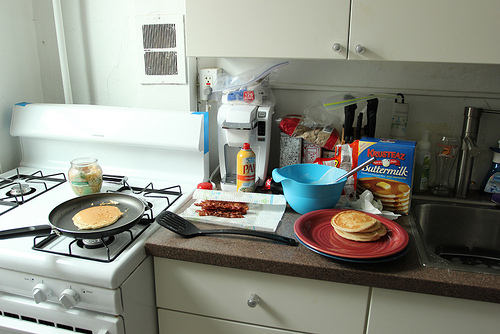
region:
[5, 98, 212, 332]
white stove top with black burners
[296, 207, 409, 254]
red plate with pancakes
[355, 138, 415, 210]
blue box of pancake mix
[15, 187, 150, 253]
black skillet cooking pancake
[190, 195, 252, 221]
stack of crispy bacon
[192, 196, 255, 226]
bacon draining on paper towel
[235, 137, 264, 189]
can of nonstick cooking spray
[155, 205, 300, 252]
black slotted turner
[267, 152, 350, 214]
blue bowl of mix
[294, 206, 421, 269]
blue plate under red plate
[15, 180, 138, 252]
pancakes in a frying pan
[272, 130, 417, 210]
buttermilk pancake mix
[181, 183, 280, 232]
bacon drying on a paper towel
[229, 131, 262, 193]
Non stick spray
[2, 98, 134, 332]
white gas stove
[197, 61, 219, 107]
white three prong electrical outlet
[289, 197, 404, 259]
pancakes stacked in a red dish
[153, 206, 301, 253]
black plastic spatula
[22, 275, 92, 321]
white gas stove knobs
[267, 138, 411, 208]
pancake mix in a blue mixing bowl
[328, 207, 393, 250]
a stack of pancakes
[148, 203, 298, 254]
a black spatula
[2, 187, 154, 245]
pancake in a frying pan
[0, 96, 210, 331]
a brand new stove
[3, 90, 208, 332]
a white gas stove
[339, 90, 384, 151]
a set of knifes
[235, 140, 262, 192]
a can of pam spray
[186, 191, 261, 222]
bacon on a paper towel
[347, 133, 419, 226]
box of buttermilk pancake mix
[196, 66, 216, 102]
a white outlet with one available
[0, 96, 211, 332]
gas stove with four burners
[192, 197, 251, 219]
bacon on paper towel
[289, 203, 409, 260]
three pancakes on red plate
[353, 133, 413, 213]
box of Krusteaz buttermilk pancake mix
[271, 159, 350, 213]
blue plastic mixing bowl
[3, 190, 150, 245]
pancake in skillet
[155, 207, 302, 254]
spatula on countertop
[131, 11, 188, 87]
exhaust vent in white wall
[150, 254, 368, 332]
closed drawer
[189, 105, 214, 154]
blue masking tape on back of stove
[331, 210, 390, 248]
Stack of pancakes on the red plate.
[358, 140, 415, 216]
Blue pancake mix box on the counter.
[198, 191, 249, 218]
Fried bacon on the paper towel.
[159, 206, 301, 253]
Black spatula on the counter next to the stack of pancakes.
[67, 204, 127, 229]
Pancake being cooked in the frying pan.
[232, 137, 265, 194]
Yellow and red PAM spray behind the bacon on the paper towel.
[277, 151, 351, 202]
Light blue bowl with the whisk in it.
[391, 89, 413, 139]
Paper towel roll on holder behind the box of pancake mix.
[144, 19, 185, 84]
Two vents on the wall above the stove.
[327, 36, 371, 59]
Two door knobs on the cabinet doors.